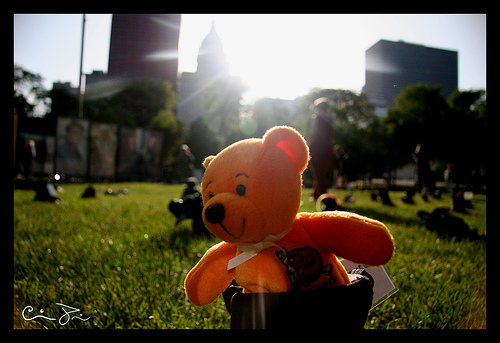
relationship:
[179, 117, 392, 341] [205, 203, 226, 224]
teddy bear has bear nose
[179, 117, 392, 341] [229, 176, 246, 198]
teddy bear has eye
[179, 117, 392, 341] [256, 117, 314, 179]
teddy bear has ear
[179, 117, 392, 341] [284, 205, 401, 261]
teddy bear has arm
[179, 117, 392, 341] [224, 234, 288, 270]
teddy bear has bow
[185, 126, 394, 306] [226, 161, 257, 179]
teddy bear has eyebrow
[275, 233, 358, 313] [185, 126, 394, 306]
beaver embroidered on teddy bear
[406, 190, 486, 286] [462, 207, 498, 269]
shadow of a person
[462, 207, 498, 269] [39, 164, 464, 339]
person in a field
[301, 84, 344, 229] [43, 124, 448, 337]
person in a field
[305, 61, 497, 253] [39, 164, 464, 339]
trees in a field